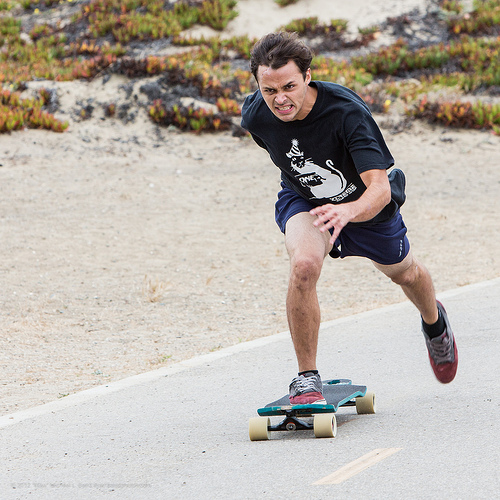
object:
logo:
[277, 132, 359, 206]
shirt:
[240, 79, 409, 211]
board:
[248, 378, 375, 440]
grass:
[1, 3, 500, 149]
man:
[239, 31, 459, 410]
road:
[0, 282, 500, 500]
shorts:
[272, 170, 409, 264]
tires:
[312, 411, 338, 438]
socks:
[298, 370, 319, 378]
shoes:
[287, 370, 328, 405]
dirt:
[15, 189, 142, 327]